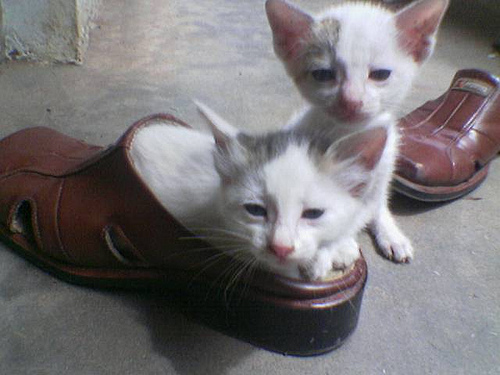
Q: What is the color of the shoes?
A: Brown.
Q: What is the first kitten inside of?
A: A shoe.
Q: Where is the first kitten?
A: Inside a shoe.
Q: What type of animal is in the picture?
A: Cat.